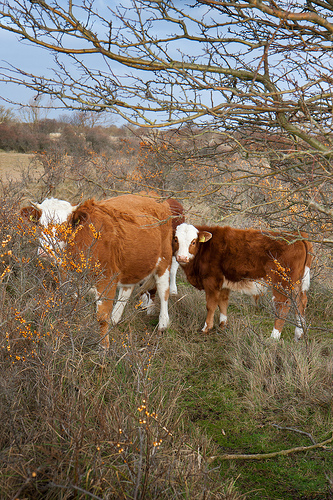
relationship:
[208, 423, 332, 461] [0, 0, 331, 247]
branches coming off tree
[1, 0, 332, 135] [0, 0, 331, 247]
sky through tree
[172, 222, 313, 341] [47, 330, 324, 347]
calf in grass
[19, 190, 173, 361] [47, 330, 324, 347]
cow in grass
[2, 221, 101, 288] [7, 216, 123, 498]
leaves on bush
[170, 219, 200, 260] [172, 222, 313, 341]
stripe on calf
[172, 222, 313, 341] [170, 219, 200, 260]
calf with stripe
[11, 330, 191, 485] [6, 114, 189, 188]
sticks on a bush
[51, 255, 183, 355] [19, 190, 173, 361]
legs of cow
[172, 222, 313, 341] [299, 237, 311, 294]
calf has short tail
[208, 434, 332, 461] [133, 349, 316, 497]
branches laying on ground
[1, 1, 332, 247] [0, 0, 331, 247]
branches of tree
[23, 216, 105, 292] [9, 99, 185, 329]
flowers blowing on tree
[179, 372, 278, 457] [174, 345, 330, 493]
patch of grass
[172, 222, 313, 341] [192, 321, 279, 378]
calf standing on grass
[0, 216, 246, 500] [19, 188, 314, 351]
bush in front of cows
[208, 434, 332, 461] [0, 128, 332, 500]
branches on field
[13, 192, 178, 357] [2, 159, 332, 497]
cow in field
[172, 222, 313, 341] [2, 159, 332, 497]
calf in field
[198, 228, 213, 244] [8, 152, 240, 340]
ear of cow'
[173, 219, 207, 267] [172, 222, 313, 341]
face of calf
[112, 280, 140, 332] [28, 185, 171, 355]
leg of cow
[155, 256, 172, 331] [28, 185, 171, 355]
leg of cow